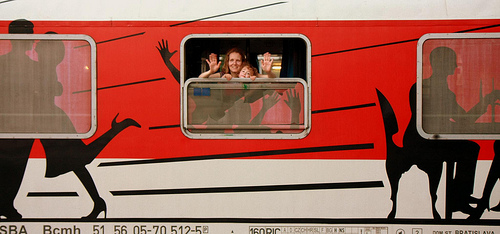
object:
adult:
[198, 47, 278, 78]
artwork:
[0, 1, 500, 227]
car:
[0, 1, 498, 232]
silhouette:
[1, 15, 65, 222]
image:
[375, 46, 500, 221]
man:
[401, 45, 500, 215]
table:
[422, 121, 500, 135]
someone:
[466, 137, 500, 221]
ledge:
[185, 76, 303, 83]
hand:
[249, 74, 257, 81]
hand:
[221, 73, 233, 81]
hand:
[259, 52, 275, 72]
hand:
[206, 53, 222, 74]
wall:
[2, 1, 500, 234]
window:
[176, 32, 314, 140]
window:
[415, 31, 500, 141]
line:
[312, 101, 378, 114]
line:
[96, 142, 375, 168]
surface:
[336, 51, 389, 88]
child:
[221, 64, 260, 82]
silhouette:
[29, 29, 142, 222]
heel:
[108, 112, 144, 131]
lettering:
[0, 222, 216, 234]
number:
[151, 223, 204, 234]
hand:
[154, 37, 178, 61]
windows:
[0, 33, 98, 141]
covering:
[180, 76, 310, 136]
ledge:
[178, 123, 312, 131]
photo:
[0, 0, 500, 234]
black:
[372, 85, 462, 220]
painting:
[109, 111, 144, 130]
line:
[108, 180, 385, 197]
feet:
[78, 196, 108, 220]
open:
[177, 31, 321, 139]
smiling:
[193, 49, 276, 81]